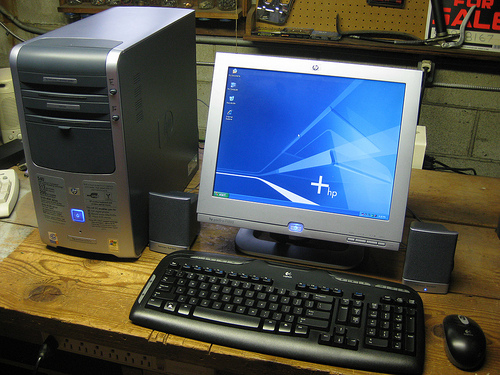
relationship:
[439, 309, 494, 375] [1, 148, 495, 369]
mouse on desk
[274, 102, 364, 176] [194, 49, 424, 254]
screen on screen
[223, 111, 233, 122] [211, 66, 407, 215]
icon on screen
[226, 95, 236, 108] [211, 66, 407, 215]
icon on screen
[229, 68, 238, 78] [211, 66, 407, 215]
icon on screen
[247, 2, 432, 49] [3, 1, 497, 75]
pegboard on wall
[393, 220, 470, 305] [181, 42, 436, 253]
speaker beside monitor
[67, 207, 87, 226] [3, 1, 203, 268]
logo on tower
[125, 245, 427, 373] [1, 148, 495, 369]
keyboard on desk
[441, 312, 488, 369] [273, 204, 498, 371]
mouse on desk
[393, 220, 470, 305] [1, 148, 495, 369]
speaker on desk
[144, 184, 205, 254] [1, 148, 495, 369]
speaker on desk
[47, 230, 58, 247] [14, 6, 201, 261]
sticker on computer